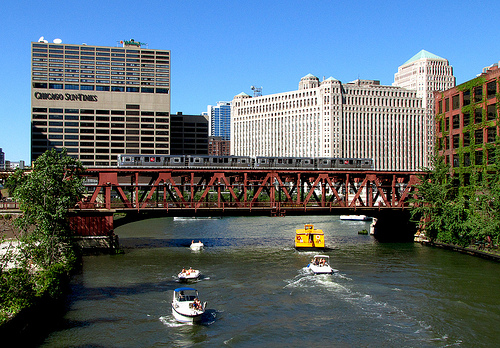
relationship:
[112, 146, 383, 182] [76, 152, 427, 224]
train above bridge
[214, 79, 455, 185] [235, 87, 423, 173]
building has windows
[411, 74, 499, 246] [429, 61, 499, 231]
ivy climbing building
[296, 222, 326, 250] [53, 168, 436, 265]
boat under bridge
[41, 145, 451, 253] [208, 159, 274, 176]
bridge has edge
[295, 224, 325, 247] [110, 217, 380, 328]
boat in water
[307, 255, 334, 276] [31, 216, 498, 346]
boat in water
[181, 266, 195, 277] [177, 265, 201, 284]
people in boat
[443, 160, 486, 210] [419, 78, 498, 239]
green vines in building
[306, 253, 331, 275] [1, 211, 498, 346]
boat on river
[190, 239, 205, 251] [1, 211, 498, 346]
boat on river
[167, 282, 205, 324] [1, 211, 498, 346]
boat on river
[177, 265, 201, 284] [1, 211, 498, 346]
boat on river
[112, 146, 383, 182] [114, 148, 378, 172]
train on bridge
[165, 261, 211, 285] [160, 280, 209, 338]
roof on boat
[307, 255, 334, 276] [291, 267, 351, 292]
boat forms wake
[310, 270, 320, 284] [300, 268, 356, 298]
part of a splash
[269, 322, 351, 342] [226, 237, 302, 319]
part of a water